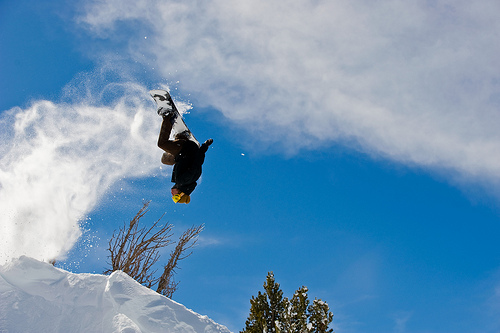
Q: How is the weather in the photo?
A: It is clear.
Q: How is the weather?
A: It is clear.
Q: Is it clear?
A: Yes, it is clear.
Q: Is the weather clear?
A: Yes, it is clear.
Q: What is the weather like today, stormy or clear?
A: It is clear.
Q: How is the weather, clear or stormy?
A: It is clear.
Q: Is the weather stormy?
A: No, it is clear.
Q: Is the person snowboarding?
A: Yes, the person is snowboarding.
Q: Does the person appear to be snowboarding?
A: Yes, the person is snowboarding.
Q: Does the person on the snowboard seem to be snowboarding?
A: Yes, the person is snowboarding.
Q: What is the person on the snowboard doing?
A: The person is snowboarding.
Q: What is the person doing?
A: The person is snowboarding.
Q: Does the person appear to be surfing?
A: No, the person is snowboarding.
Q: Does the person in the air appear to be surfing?
A: No, the person is snowboarding.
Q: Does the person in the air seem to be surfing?
A: No, the person is snowboarding.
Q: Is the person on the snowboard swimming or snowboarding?
A: The person is snowboarding.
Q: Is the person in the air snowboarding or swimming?
A: The person is snowboarding.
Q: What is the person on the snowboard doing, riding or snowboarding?
A: The person is snowboarding.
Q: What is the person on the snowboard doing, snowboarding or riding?
A: The person is snowboarding.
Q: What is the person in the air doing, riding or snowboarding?
A: The person is snowboarding.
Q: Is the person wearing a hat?
A: Yes, the person is wearing a hat.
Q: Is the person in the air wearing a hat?
A: Yes, the person is wearing a hat.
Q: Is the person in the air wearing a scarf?
A: No, the person is wearing a hat.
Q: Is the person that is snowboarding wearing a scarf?
A: No, the person is wearing a hat.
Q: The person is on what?
A: The person is on the snowboard.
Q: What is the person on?
A: The person is on the snowboard.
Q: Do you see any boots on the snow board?
A: No, there is a person on the snow board.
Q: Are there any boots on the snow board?
A: No, there is a person on the snow board.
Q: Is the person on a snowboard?
A: Yes, the person is on a snowboard.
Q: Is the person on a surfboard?
A: No, the person is on a snowboard.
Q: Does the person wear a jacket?
A: Yes, the person wears a jacket.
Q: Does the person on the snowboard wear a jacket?
A: Yes, the person wears a jacket.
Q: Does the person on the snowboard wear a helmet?
A: No, the person wears a jacket.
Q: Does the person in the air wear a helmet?
A: No, the person wears a jacket.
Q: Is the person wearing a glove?
A: Yes, the person is wearing a glove.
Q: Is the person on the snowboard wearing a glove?
A: Yes, the person is wearing a glove.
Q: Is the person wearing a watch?
A: No, the person is wearing a glove.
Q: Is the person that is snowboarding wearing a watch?
A: No, the person is wearing a glove.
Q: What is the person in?
A: The person is in the air.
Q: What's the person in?
A: The person is in the air.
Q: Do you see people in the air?
A: Yes, there is a person in the air.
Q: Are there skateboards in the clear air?
A: No, there is a person in the air.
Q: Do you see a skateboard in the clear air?
A: No, there is a person in the air.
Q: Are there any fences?
A: No, there are no fences.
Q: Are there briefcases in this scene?
A: No, there are no briefcases.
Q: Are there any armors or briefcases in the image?
A: No, there are no briefcases or armors.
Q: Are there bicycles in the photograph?
A: No, there are no bicycles.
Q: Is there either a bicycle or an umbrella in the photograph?
A: No, there are no bicycles or umbrellas.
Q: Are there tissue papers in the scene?
A: No, there are no tissue papers.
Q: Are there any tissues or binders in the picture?
A: No, there are no tissues or binders.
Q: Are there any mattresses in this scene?
A: No, there are no mattresses.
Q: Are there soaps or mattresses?
A: No, there are no mattresses or soaps.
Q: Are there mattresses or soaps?
A: No, there are no mattresses or soaps.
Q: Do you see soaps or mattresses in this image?
A: No, there are no mattresses or soaps.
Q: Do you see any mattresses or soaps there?
A: No, there are no mattresses or soaps.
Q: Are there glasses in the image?
A: No, there are no glasses.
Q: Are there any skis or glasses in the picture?
A: No, there are no glasses or skis.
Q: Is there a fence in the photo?
A: No, there are no fences.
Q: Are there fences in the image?
A: No, there are no fences.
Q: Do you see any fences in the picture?
A: No, there are no fences.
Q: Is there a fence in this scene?
A: No, there are no fences.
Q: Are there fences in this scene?
A: No, there are no fences.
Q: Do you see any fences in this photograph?
A: No, there are no fences.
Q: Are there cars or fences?
A: No, there are no fences or cars.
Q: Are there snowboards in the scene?
A: Yes, there is a snowboard.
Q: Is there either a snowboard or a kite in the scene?
A: Yes, there is a snowboard.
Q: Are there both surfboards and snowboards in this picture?
A: No, there is a snowboard but no surfboards.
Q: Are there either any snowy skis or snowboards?
A: Yes, there is a snowy snowboard.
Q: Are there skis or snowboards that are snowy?
A: Yes, the snowboard is snowy.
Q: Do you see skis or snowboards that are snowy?
A: Yes, the snowboard is snowy.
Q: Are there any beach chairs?
A: No, there are no beach chairs.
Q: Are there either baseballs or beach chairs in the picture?
A: No, there are no beach chairs or baseballs.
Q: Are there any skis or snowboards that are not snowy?
A: No, there is a snowboard but it is snowy.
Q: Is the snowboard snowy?
A: Yes, the snowboard is snowy.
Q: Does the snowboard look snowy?
A: Yes, the snowboard is snowy.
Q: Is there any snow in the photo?
A: Yes, there is snow.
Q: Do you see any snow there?
A: Yes, there is snow.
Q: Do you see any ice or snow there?
A: Yes, there is snow.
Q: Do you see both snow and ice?
A: No, there is snow but no ice.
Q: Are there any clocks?
A: No, there are no clocks.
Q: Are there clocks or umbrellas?
A: No, there are no clocks or umbrellas.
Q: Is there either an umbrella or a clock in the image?
A: No, there are no clocks or umbrellas.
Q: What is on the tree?
A: The snow is on the tree.